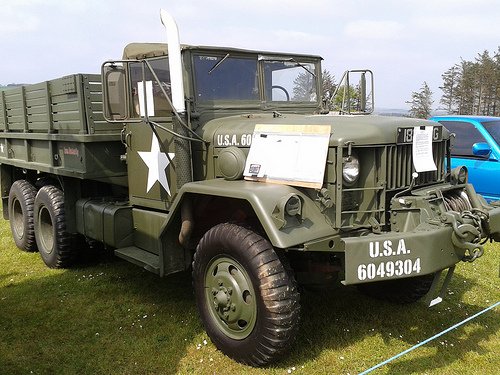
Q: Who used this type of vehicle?
A: Military.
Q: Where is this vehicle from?
A: America.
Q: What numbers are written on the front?
A: 6049304.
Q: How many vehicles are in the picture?
A: 2.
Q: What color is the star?
A: White.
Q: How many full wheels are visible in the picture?
A: 3.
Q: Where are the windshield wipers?
A: Top of windshield.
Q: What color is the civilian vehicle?
A: Blue.